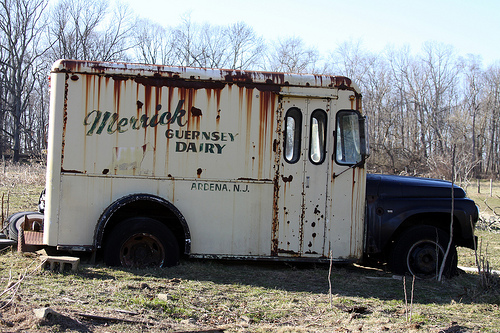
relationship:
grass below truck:
[2, 159, 499, 332] [41, 58, 476, 280]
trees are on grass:
[0, 0, 498, 181] [2, 159, 499, 332]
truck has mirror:
[41, 58, 476, 280] [333, 110, 363, 164]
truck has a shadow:
[41, 58, 476, 280] [48, 256, 499, 303]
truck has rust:
[41, 58, 476, 280] [62, 60, 281, 158]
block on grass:
[42, 256, 77, 272] [2, 159, 499, 332]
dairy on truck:
[175, 140, 225, 155] [41, 58, 476, 280]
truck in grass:
[41, 58, 476, 280] [2, 159, 499, 332]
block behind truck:
[42, 256, 77, 272] [41, 58, 476, 280]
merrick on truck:
[84, 97, 187, 132] [41, 58, 476, 280]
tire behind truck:
[10, 210, 44, 241] [41, 58, 476, 280]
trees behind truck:
[0, 0, 498, 181] [41, 58, 476, 280]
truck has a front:
[41, 58, 476, 280] [366, 175, 479, 262]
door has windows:
[276, 94, 328, 256] [285, 108, 328, 165]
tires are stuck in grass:
[105, 217, 456, 279] [2, 159, 499, 332]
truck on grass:
[41, 58, 476, 280] [2, 159, 499, 332]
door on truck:
[276, 94, 328, 256] [41, 58, 476, 280]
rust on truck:
[62, 60, 281, 158] [41, 58, 476, 280]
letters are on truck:
[83, 98, 248, 192] [41, 58, 476, 280]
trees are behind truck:
[0, 0, 498, 181] [41, 58, 476, 280]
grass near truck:
[2, 159, 499, 332] [41, 58, 476, 280]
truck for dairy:
[41, 58, 476, 280] [175, 140, 225, 155]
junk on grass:
[1, 212, 79, 272] [2, 159, 499, 332]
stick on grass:
[2, 269, 20, 309] [2, 159, 499, 332]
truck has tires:
[41, 58, 476, 280] [105, 217, 456, 279]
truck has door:
[41, 58, 476, 280] [276, 94, 328, 256]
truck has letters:
[41, 58, 476, 280] [83, 98, 248, 192]